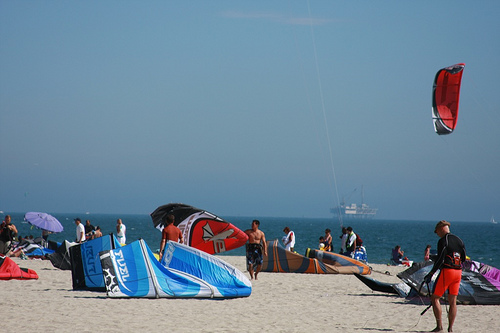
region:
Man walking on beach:
[415, 207, 465, 327]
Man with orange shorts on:
[415, 260, 465, 325]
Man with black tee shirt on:
[415, 210, 475, 275]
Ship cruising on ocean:
[311, 163, 416, 221]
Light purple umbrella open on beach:
[15, 191, 67, 251]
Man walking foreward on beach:
[232, 205, 289, 295]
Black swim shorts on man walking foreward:
[235, 236, 278, 288]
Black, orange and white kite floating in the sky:
[401, 41, 496, 153]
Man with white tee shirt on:
[60, 198, 103, 249]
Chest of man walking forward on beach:
[238, 227, 270, 247]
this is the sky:
[122, 14, 182, 98]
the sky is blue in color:
[98, 34, 169, 69]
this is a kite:
[431, 60, 468, 150]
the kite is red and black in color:
[431, 96, 448, 131]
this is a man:
[430, 217, 470, 331]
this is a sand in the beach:
[267, 278, 328, 329]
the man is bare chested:
[251, 230, 261, 241]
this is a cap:
[436, 217, 450, 223]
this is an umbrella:
[29, 210, 63, 230]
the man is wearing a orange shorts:
[443, 270, 460, 287]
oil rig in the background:
[328, 180, 381, 228]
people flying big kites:
[322, 221, 375, 265]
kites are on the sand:
[67, 202, 374, 298]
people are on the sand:
[240, 218, 399, 290]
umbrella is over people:
[25, 210, 62, 257]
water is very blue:
[93, 213, 498, 248]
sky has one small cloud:
[230, 6, 327, 31]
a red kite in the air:
[428, 61, 467, 135]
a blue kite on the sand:
[94, 236, 256, 302]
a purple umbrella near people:
[23, 209, 66, 239]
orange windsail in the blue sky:
[410, 50, 474, 170]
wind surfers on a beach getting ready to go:
[1, 183, 494, 319]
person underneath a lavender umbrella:
[10, 190, 70, 255]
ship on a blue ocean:
[315, 162, 405, 238]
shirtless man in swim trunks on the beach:
[243, 217, 272, 287]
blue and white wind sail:
[61, 232, 267, 319]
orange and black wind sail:
[134, 191, 251, 263]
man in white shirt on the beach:
[279, 212, 304, 251]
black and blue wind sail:
[65, 243, 117, 302]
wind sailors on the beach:
[6, 163, 379, 316]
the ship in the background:
[329, 180, 388, 223]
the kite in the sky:
[425, 58, 475, 151]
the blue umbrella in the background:
[12, 209, 70, 235]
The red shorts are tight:
[429, 263, 467, 310]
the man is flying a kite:
[420, 202, 478, 326]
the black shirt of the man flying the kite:
[421, 230, 471, 266]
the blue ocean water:
[1, 205, 497, 282]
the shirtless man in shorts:
[245, 215, 273, 287]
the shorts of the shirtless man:
[245, 245, 266, 270]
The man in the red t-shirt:
[150, 212, 189, 247]